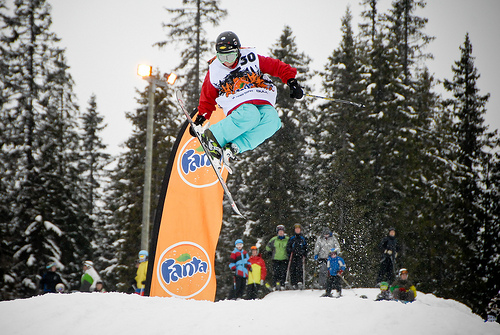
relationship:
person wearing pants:
[189, 33, 304, 164] [208, 104, 283, 154]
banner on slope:
[149, 101, 232, 301] [1, 287, 500, 334]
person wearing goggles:
[189, 33, 304, 164] [216, 49, 241, 63]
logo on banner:
[157, 241, 212, 299] [149, 101, 232, 301]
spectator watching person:
[324, 250, 348, 298] [189, 33, 304, 164]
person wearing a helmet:
[189, 33, 304, 164] [213, 31, 241, 51]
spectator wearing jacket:
[324, 250, 348, 298] [324, 255, 348, 277]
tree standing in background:
[9, 1, 62, 181] [0, 0, 484, 312]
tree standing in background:
[8, 115, 99, 300] [0, 0, 484, 312]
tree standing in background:
[74, 90, 112, 229] [0, 0, 484, 312]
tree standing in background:
[318, 8, 368, 155] [0, 0, 484, 312]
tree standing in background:
[257, 27, 317, 254] [0, 0, 484, 312]